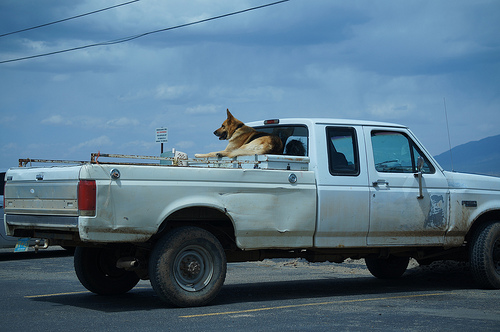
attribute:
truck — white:
[2, 116, 491, 308]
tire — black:
[148, 228, 226, 304]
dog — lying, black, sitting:
[194, 109, 281, 158]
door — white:
[364, 126, 448, 250]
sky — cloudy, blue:
[2, 2, 497, 167]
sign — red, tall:
[155, 127, 167, 142]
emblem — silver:
[464, 200, 478, 208]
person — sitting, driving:
[288, 141, 305, 155]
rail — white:
[90, 152, 267, 168]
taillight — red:
[77, 180, 95, 209]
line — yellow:
[180, 291, 460, 320]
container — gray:
[186, 155, 309, 171]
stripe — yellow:
[177, 289, 445, 321]